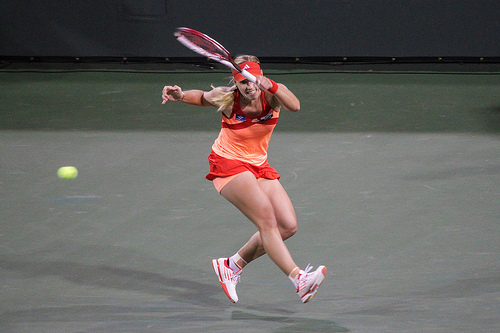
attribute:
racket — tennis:
[171, 22, 261, 84]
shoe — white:
[259, 253, 367, 325]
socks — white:
[229, 251, 307, 284]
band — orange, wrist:
[263, 77, 279, 102]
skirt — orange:
[200, 144, 289, 181]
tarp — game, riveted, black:
[336, 0, 499, 67]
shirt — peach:
[210, 111, 279, 165]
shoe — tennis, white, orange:
[210, 255, 247, 307]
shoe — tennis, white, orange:
[294, 261, 329, 308]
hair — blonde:
[209, 77, 239, 117]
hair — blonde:
[227, 53, 264, 65]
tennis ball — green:
[46, 159, 83, 182]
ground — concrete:
[10, 224, 153, 315]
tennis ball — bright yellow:
[57, 166, 81, 183]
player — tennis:
[160, 48, 324, 305]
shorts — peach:
[208, 172, 236, 194]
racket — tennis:
[157, 14, 234, 78]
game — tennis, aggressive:
[4, 2, 497, 331]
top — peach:
[210, 103, 277, 164]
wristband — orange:
[263, 78, 282, 97]